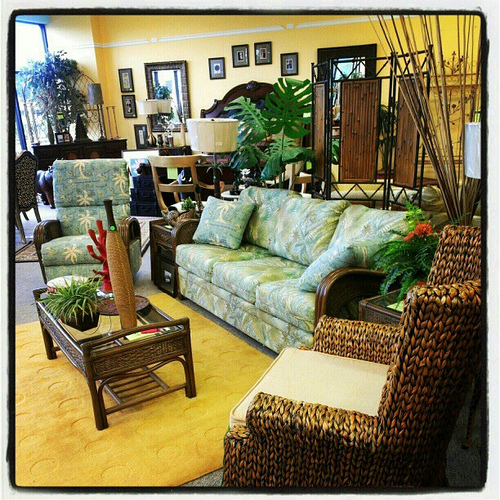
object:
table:
[31, 282, 196, 431]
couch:
[174, 184, 448, 356]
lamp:
[135, 99, 159, 148]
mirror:
[326, 55, 367, 121]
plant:
[17, 50, 90, 140]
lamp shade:
[185, 117, 238, 153]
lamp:
[86, 82, 107, 141]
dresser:
[30, 137, 128, 205]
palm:
[224, 74, 313, 192]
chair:
[218, 225, 477, 489]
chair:
[33, 157, 143, 286]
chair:
[16, 147, 39, 243]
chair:
[130, 147, 191, 217]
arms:
[33, 217, 60, 244]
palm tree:
[73, 159, 88, 180]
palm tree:
[112, 168, 130, 197]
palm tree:
[62, 243, 82, 265]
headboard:
[200, 79, 310, 147]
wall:
[93, 18, 481, 188]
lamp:
[185, 117, 238, 200]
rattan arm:
[315, 265, 403, 318]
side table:
[149, 211, 201, 299]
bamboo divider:
[308, 41, 433, 214]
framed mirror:
[150, 70, 184, 126]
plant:
[374, 201, 469, 306]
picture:
[232, 44, 250, 67]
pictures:
[117, 68, 134, 93]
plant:
[38, 270, 103, 326]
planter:
[59, 299, 102, 332]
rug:
[14, 291, 273, 486]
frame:
[143, 60, 192, 133]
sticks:
[365, 14, 478, 223]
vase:
[408, 281, 426, 289]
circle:
[58, 397, 83, 411]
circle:
[71, 416, 92, 430]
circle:
[48, 379, 71, 393]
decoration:
[100, 195, 138, 330]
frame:
[310, 43, 434, 84]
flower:
[404, 218, 434, 242]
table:
[355, 283, 417, 324]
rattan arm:
[245, 389, 379, 464]